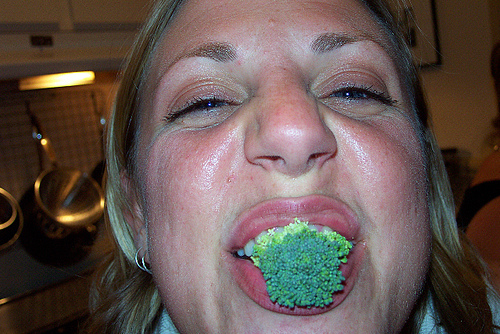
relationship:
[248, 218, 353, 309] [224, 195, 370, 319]
broccoli in girl's mouth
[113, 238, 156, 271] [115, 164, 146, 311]
earring in a womans ear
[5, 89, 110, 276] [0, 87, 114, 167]
cooking tools on peg board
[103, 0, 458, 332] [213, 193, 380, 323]
girl in womans mouth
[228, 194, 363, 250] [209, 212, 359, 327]
lip on womans mouth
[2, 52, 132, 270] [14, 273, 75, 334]
pots hanging in back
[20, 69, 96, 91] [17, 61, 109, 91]
light turned on light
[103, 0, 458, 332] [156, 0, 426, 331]
girl has face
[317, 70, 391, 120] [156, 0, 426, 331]
eye on face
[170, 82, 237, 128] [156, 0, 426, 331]
eye on face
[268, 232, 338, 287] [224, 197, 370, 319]
broccoli in girl's mouth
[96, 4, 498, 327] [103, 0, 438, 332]
hair of girl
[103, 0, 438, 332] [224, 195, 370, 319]
girl has girl's mouth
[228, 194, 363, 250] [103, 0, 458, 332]
lip on girl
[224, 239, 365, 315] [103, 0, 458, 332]
lip on girl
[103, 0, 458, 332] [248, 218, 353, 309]
girl eating broccoli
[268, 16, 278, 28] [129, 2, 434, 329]
pimple on face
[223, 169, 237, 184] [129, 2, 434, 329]
pimple on face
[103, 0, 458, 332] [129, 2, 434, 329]
girl has face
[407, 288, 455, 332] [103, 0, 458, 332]
white collar on girl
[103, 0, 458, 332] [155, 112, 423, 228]
girl has acne